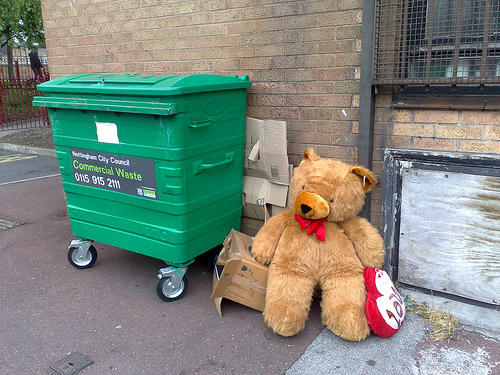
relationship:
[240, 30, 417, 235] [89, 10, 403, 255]
bricks on building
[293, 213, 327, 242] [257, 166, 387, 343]
ribbon on bear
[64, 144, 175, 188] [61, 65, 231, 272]
sticker on bin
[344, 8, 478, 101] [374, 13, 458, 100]
fence on window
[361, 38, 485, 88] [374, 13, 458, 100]
bars on window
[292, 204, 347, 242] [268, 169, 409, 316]
bow on bear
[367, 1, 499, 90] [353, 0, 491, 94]
gate on window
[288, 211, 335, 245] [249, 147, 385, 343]
ribbon around bear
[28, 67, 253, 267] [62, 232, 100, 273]
garbage on wheel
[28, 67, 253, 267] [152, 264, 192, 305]
garbage on wheel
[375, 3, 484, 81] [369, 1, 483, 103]
bars on window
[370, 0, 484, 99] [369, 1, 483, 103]
wire on window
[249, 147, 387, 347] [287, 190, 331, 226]
bear with nose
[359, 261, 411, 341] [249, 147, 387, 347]
heart leaning on bear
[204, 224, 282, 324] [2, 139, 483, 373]
box on ground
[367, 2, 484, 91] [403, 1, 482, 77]
gate on window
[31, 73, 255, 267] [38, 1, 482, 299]
bin next to wall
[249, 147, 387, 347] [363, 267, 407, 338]
bear with heart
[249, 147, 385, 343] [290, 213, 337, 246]
bear with ribbon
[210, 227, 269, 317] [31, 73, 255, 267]
box next to bin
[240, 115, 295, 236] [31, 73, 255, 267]
box next to bin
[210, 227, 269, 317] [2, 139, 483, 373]
box on ground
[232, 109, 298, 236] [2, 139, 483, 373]
box on ground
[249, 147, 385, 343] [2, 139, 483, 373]
bear on ground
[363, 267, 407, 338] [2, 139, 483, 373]
heart on ground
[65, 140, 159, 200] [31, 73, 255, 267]
sign on bin